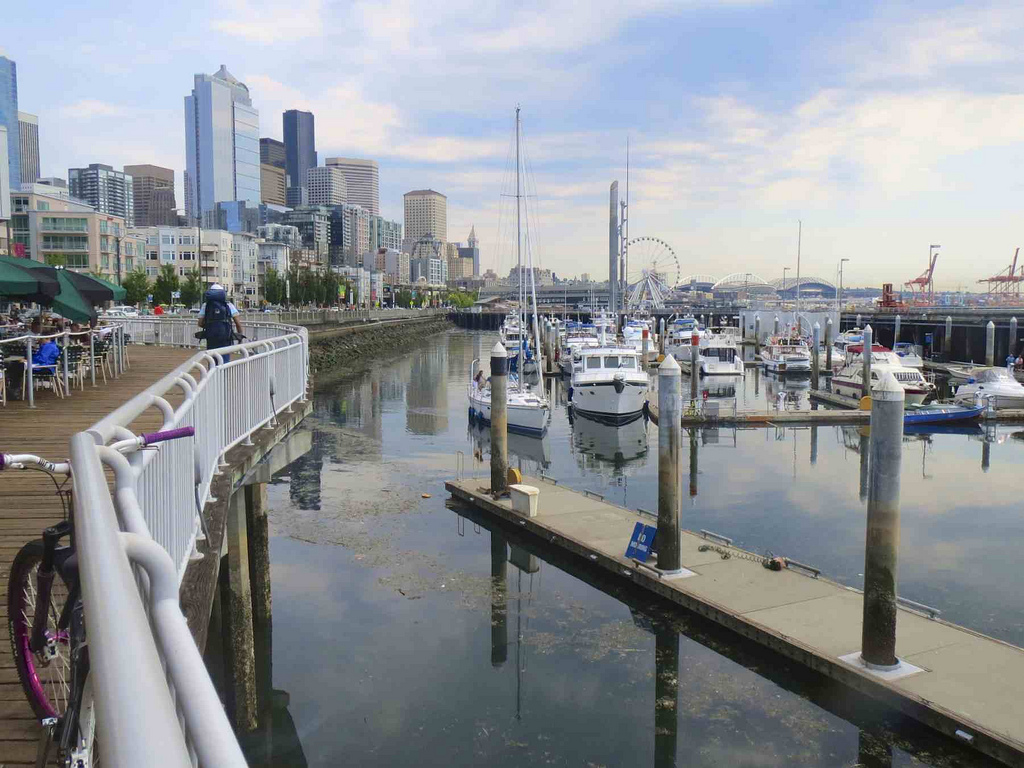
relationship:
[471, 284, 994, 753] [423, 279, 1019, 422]
marina filled with boats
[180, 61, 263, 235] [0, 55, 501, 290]
glass building of buildings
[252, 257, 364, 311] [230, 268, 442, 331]
trees on street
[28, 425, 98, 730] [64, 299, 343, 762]
bicycle tied to rail